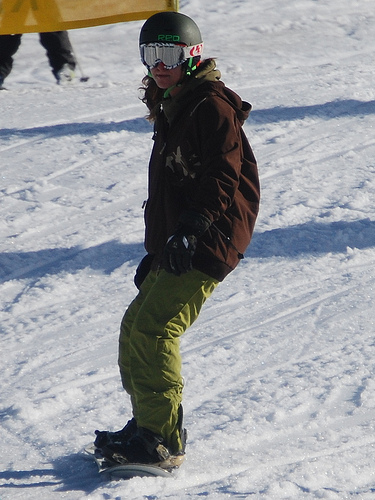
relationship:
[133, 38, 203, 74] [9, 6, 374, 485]
goggles are for snow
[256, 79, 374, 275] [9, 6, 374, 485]
shadows on snow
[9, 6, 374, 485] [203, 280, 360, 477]
snow has tracks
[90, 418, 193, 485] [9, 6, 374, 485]
snow board on snow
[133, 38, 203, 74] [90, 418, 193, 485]
googles for snowboard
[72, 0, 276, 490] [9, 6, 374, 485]
female snowboard on snow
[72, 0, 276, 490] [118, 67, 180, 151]
young female has long hair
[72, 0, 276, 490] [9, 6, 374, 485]
woman snowboarding on snow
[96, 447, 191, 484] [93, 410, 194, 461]
snow board has bindings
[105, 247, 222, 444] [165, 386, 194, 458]
snow pants have side zipper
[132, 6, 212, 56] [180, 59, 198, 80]
helmet has green strap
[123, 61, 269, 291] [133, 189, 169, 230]
jacket has camo pocket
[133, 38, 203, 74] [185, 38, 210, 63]
goggles has red straps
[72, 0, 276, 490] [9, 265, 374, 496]
snowboarder at end of hill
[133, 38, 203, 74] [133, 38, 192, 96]
goggles covers face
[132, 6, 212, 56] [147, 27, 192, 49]
helmet has green letters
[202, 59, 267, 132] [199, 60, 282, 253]
jacket hood on back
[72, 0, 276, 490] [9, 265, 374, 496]
snowboard down slope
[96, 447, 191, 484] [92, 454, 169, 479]
snowboard has rounded edge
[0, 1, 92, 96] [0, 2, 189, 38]
legs behind banner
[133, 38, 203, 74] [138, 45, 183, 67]
goggles on eyes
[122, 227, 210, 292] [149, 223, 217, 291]
hands inside glove